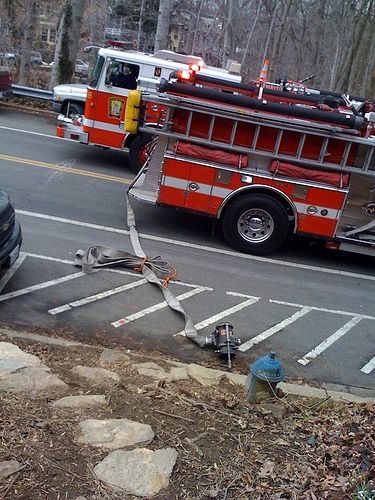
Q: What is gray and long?
A: Fire hose.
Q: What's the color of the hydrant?
A: Blue.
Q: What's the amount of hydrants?
A: One.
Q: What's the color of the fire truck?
A: Red.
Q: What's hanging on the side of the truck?
A: Ladder.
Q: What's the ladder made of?
A: Metal.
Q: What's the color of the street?
A: Grey.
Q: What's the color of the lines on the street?
A: White.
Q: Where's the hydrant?
A: Curbside.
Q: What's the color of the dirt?
A: Brown.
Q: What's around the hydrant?
A: Dirt.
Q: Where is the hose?
A: On the street.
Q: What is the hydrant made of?
A: Metal.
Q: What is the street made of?
A: Asphalt.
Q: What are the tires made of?
A: Rubber.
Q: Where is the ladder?
A: On the fire engine.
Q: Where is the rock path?
A: Behind the hydrant.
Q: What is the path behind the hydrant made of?
A: Rocks.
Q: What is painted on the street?
A: White and yellow lines.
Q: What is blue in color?
A: Fire hydrant.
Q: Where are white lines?
A: On the pavement.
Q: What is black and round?
A: Tires.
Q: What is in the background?
A: Trees.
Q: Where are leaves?
A: On the ground.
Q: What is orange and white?
A: Traffic cone.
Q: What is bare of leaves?
A: The trees.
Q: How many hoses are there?
A: One.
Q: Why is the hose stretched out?
A: It has been used.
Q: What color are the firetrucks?
A: Red.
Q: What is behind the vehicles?
A: Trees.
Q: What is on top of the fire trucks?
A: Flashing lights.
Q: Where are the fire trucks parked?
A: In the road.